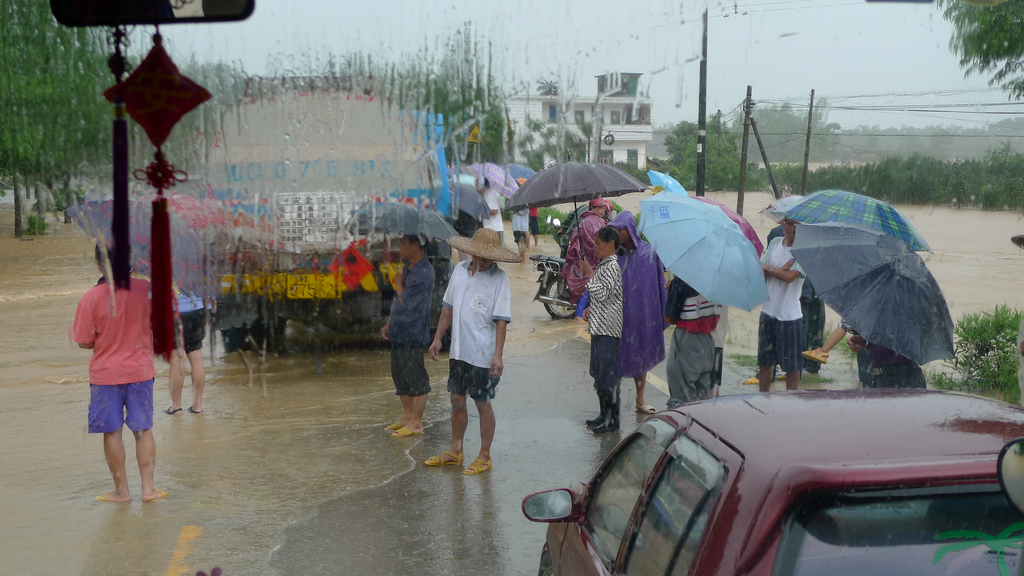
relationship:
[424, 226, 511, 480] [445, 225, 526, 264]
man has hat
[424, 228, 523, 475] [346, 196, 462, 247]
man hold umbrella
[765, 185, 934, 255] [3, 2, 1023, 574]
umbrella in rain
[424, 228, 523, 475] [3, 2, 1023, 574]
man in rain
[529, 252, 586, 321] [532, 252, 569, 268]
motorcycle has back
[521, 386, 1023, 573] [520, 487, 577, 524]
car has mirror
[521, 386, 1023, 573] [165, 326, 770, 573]
car in street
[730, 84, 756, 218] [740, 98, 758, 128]
pole has light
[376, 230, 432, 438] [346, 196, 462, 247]
man holds umbrella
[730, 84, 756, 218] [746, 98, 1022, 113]
pole has wire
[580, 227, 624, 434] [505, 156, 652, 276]
pedestrians has umbrella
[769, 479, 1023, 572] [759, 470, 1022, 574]
water on windshield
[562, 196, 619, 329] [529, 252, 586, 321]
person on motorbike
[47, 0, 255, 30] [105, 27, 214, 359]
mirror has ornament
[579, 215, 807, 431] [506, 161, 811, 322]
pedestrians with umbrellas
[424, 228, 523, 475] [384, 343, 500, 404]
man wear shorts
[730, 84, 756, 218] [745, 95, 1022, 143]
pole has lines